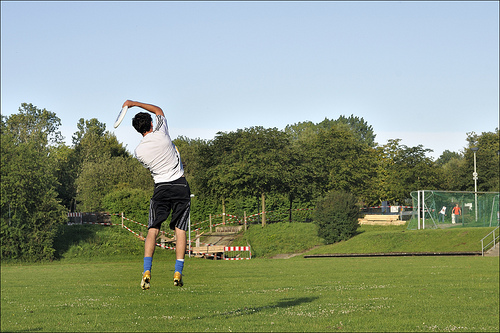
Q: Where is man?
A: Green Field.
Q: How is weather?
A: Sunny and clear.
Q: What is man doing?
A: Jumping to catch frisbee.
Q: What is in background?
A: Green Trees.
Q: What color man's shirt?
A: White.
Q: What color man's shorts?
A: Black.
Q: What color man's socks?
A: Blue.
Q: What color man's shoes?
A: Yellow.